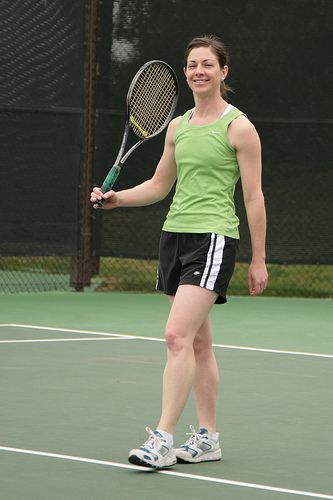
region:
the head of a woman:
[167, 22, 262, 118]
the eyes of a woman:
[176, 50, 234, 87]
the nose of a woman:
[179, 58, 217, 81]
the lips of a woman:
[190, 72, 219, 87]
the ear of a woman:
[211, 53, 252, 92]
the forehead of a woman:
[183, 31, 225, 67]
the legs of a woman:
[134, 268, 265, 474]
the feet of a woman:
[118, 383, 243, 473]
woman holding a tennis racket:
[69, 145, 137, 213]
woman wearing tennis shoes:
[124, 416, 222, 474]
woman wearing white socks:
[151, 427, 175, 450]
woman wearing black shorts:
[143, 220, 227, 308]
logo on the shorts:
[189, 264, 206, 287]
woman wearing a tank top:
[170, 101, 251, 255]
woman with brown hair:
[179, 31, 228, 79]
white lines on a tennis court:
[28, 429, 145, 477]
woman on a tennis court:
[98, 67, 324, 321]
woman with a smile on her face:
[185, 71, 218, 88]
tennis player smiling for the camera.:
[92, 34, 271, 467]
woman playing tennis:
[87, 24, 299, 474]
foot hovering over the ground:
[124, 429, 185, 472]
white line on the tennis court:
[0, 444, 332, 497]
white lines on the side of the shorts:
[196, 232, 228, 293]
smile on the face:
[190, 74, 211, 85]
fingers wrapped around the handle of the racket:
[91, 188, 114, 209]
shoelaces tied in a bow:
[184, 425, 208, 441]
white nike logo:
[207, 128, 224, 135]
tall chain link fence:
[0, 1, 332, 298]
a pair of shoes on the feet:
[120, 422, 227, 471]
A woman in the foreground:
[87, 28, 285, 474]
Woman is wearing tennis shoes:
[123, 411, 230, 477]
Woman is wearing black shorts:
[142, 224, 247, 437]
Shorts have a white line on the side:
[196, 222, 228, 292]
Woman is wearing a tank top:
[150, 93, 261, 249]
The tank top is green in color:
[150, 97, 254, 240]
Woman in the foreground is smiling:
[175, 28, 241, 111]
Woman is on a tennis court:
[2, 3, 331, 499]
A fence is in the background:
[3, 1, 331, 299]